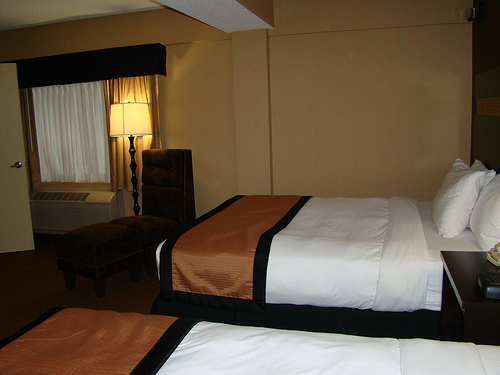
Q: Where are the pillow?
A: On the far bed.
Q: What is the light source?
A: A floor lamp.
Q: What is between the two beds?
A: A night stand.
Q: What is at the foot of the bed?
A: A chair and ottoman.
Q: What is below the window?
A: A heater.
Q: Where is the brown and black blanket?
A: On the bed.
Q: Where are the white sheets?
A: On the bed.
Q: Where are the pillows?
A: On the bed.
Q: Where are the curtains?
A: On the window.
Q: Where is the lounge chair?
A: At the foot of the bed.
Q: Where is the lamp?
A: Next to the lounge chair.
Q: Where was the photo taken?
A: In a hotel room.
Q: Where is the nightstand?
A: In between the beds.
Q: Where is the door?
A: Next to the window.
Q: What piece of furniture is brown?
A: The lounge chair.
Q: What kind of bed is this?
A: A large bed.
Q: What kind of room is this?
A: A hotel room.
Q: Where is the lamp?
A: Near the window.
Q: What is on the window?
A: A curtain.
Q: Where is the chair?
A: Near the lamp.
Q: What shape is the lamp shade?
A: Round.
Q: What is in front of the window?
A: A heater.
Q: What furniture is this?
A: A bed.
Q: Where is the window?
A: On the left.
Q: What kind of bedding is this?
A: White.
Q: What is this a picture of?
A: A hotel room.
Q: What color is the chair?
A: Brown.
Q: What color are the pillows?
A: White.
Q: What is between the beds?
A: A nightstand.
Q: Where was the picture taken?
A: In a hotel room.